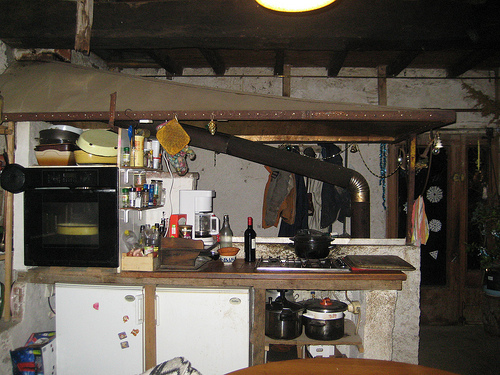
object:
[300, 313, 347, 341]
pots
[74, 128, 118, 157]
pots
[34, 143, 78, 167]
pots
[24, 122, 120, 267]
shelf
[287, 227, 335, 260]
pot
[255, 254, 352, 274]
burner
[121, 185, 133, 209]
spices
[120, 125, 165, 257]
shelf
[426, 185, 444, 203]
snowflake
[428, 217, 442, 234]
snowflake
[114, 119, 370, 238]
pipe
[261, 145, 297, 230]
coats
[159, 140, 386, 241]
wall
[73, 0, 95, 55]
brown beam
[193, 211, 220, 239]
pot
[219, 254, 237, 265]
bowl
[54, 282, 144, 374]
fridge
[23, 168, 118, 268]
black oven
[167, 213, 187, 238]
box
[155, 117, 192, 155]
oven mitt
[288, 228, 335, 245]
black lid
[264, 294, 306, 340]
pots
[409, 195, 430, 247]
towel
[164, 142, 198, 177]
glove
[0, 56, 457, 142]
canopy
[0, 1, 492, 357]
kitchen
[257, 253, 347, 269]
stovetop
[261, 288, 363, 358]
shelf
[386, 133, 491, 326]
door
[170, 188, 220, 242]
coffee maker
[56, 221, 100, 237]
pan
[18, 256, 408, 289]
counter